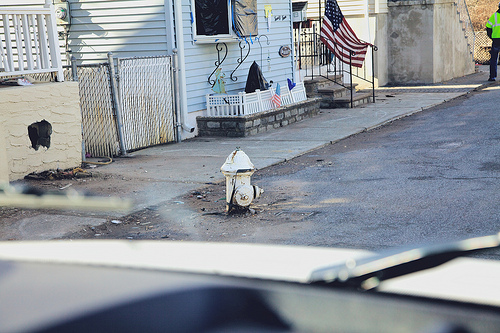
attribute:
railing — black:
[305, 41, 352, 90]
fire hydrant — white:
[218, 147, 265, 212]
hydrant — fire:
[209, 140, 297, 241]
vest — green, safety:
[486, 11, 499, 43]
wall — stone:
[46, 17, 494, 143]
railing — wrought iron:
[302, 36, 379, 107]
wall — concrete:
[30, 11, 370, 166]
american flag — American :
[305, 7, 370, 83]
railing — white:
[3, 9, 59, 70]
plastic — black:
[197, 1, 225, 31]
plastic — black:
[236, 3, 256, 35]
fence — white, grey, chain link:
[12, 47, 191, 171]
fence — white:
[68, 53, 162, 154]